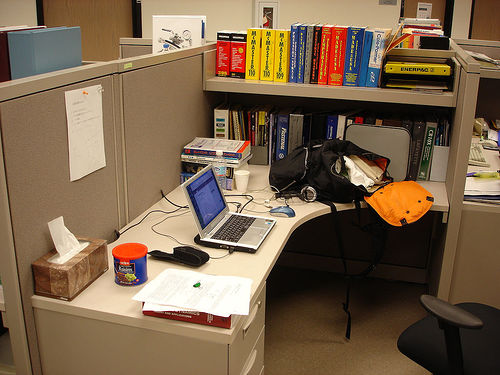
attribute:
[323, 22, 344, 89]
book — red 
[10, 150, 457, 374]
cubicle — divider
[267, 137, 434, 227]
bag — black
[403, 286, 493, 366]
chair — black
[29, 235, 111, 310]
box — tissues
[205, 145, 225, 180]
bottle — water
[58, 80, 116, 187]
paper — pinned